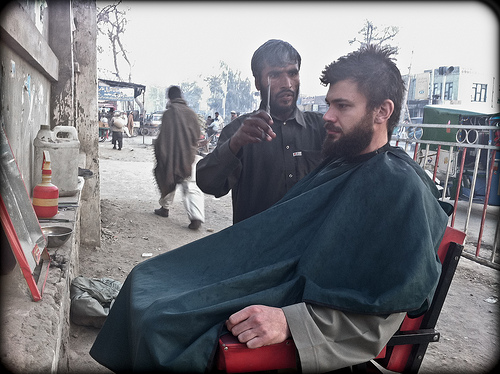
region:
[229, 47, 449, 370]
Man getting hair cut.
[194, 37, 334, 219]
Man cutting hair.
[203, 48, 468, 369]
Man sitting in red chair.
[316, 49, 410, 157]
Man wearing a beard.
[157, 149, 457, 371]
Dark green hair apron.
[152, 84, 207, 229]
Man in white pants walking.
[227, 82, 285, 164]
Man holding scissors in hand.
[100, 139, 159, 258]
Loose dirt on ground.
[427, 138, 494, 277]
Red and white metal fence.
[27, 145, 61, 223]
Red and white can on ledge.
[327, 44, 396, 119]
man has spiky hair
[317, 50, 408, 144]
man has brown hair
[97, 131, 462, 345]
man wears green cape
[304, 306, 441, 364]
man wears olive green shirt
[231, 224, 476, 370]
man sits in red chair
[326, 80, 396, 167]
man has facial hair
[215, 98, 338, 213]
barber has grey shirt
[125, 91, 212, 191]
man wears brown cape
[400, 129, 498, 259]
grey and red rails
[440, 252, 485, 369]
grey and dry ground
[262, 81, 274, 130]
scissors in the man's hand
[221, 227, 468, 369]
red barber chair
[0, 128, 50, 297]
small mirror on the ledge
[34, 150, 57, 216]
red and white container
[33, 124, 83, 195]
white gas can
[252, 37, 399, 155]
two men with facial hair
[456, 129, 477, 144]
round accent on metal fence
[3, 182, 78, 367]
concrete ledge on the wall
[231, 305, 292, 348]
man's left hand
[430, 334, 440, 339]
metal bolt on the chair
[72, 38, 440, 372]
a man in a chiar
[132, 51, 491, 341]
a man having his hair cut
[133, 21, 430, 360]
a man sitting outside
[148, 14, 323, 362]
a man sitting in a chiar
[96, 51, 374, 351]
a man sitting in a red chair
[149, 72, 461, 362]
a man sitting in a red chair outside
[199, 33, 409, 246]
a man holding scissors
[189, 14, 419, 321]
a man standing with scissors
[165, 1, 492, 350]
a man cutting hair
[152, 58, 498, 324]
a man with a cape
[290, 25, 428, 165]
A man with a hipster hairstyle.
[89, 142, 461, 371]
A large blue protective cloth.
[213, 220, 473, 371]
a red chair near a wall.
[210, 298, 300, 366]
a left human hand.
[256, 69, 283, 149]
a sharp pair of scissors.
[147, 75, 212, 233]
A man wearing a blanket over his body.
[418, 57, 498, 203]
a multi story building.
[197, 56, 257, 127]
A leaf filled tree.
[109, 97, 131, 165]
a person walking down a street.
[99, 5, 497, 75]
a gray hazy sky.